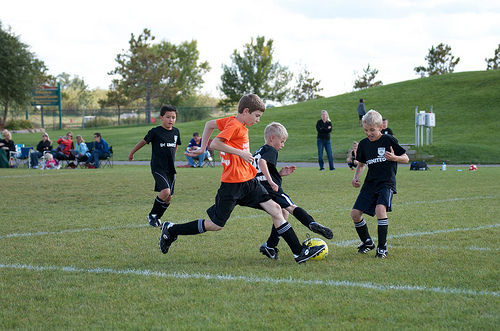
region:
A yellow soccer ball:
[303, 235, 331, 262]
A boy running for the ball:
[157, 92, 324, 265]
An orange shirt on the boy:
[211, 112, 259, 182]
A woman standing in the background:
[314, 107, 338, 171]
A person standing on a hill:
[354, 96, 368, 125]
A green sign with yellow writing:
[23, 80, 62, 130]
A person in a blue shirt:
[88, 131, 114, 168]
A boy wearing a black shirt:
[346, 108, 411, 263]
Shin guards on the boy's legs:
[351, 216, 389, 248]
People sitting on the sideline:
[0, 128, 117, 170]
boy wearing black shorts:
[167, 98, 315, 263]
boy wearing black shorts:
[261, 124, 329, 252]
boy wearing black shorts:
[344, 117, 404, 255]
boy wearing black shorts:
[138, 109, 180, 224]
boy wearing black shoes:
[172, 97, 322, 262]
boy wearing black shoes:
[259, 122, 334, 258]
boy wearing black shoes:
[336, 110, 407, 255]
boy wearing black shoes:
[138, 108, 181, 225]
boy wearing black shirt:
[346, 110, 404, 254]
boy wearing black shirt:
[136, 112, 181, 232]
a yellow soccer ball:
[291, 229, 338, 264]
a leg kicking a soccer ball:
[271, 216, 332, 266]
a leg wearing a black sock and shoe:
[248, 188, 337, 275]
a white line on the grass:
[122, 259, 482, 310]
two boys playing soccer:
[198, 91, 325, 264]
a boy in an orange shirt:
[202, 84, 269, 214]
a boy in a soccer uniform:
[343, 108, 405, 252]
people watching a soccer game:
[3, 108, 121, 172]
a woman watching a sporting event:
[305, 101, 342, 173]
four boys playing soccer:
[134, 91, 436, 273]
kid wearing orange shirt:
[151, 93, 332, 268]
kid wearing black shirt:
[349, 112, 409, 259]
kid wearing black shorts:
[124, 94, 195, 231]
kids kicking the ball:
[145, 87, 348, 264]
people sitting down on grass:
[6, 123, 117, 173]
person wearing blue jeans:
[309, 105, 339, 175]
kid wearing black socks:
[332, 102, 419, 264]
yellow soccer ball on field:
[299, 231, 333, 260]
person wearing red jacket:
[48, 128, 77, 161]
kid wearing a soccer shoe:
[335, 108, 415, 264]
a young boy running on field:
[158, 93, 325, 264]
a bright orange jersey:
[213, 116, 256, 182]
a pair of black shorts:
[204, 176, 271, 228]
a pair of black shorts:
[350, 185, 392, 217]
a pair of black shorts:
[276, 189, 293, 204]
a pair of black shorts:
[150, 164, 177, 194]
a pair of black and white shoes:
[158, 219, 176, 254]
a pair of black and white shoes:
[290, 241, 322, 261]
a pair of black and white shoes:
[353, 237, 373, 255]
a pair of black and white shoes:
[373, 243, 387, 259]